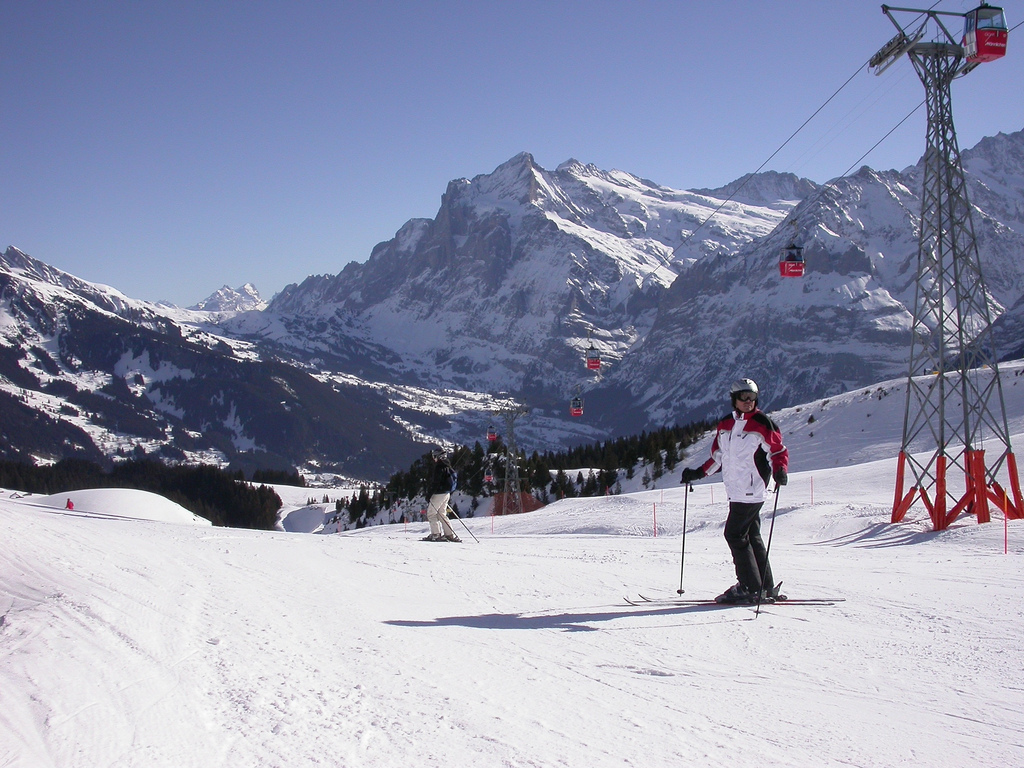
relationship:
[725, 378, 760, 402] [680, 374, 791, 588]
helmet on skier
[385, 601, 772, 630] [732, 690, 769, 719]
shadow on ground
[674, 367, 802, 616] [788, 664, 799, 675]
person on snow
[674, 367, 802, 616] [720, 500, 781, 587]
person wears pants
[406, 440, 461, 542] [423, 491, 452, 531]
skier in trousers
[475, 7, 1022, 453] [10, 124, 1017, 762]
cable lines running up mountain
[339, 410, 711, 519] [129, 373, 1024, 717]
trees along ski run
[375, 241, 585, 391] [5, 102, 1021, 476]
snow on a mountain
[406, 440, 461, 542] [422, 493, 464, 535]
skier wearing pants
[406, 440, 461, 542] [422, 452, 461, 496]
skier wearing a jacket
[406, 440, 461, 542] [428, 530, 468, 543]
skier on skis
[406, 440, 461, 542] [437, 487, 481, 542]
skier holding ski pole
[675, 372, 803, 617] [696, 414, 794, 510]
person wearing a jacket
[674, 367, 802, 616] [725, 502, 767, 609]
person wearing pants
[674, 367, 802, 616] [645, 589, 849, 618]
person on skis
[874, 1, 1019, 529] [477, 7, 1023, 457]
tower for cable lines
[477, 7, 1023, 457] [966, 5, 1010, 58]
cable lines for gondola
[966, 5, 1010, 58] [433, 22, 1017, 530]
gondola for ski lift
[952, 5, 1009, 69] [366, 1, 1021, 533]
gondola on a ski lift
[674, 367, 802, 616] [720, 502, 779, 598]
person with pants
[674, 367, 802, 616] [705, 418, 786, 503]
person with parka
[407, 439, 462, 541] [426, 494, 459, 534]
skier with pants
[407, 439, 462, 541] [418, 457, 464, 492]
skier with parka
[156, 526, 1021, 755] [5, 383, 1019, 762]
ski tracks in snow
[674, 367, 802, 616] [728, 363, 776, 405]
person wears helmet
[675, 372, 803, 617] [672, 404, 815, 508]
person wears jacket